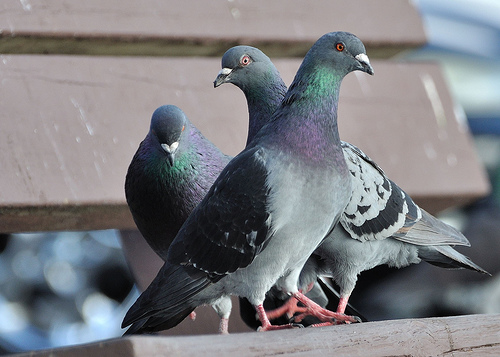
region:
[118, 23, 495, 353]
Three pigeons are standing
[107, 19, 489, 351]
Pigeons are all looking different ways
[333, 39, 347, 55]
Pigeon's eye is orange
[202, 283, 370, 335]
Pigeons' feet are pink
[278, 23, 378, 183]
Pigeon has green and purple on neck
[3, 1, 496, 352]
Pigeons are on a bench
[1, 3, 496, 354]
Bench is made of wood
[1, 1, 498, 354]
Bench is brown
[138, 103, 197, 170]
Pigeon is looking evil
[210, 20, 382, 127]
Their heads are facing opposite ways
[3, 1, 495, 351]
pigeons on a dark brown park bench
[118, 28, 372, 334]
green purple black and tan pigeon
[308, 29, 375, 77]
head of a pigeon with a brown eye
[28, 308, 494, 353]
piece of cracked wood in the seat of a bench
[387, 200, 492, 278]
long gray tail feathers of a pigeon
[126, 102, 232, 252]
blue green and purple pigeon looking down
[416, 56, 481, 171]
pigeon droppings on a back of a park bench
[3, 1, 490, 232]
two boards on the back of a park bench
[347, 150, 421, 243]
black stripes on the wing of a pigeon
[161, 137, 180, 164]
beak of a pigeon with white markings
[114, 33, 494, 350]
Three pigeons standing together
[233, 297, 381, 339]
red legs of pigeons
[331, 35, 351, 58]
orange eye of pigeon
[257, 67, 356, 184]
green and purple on pigeon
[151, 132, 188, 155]
white on beak of pigeon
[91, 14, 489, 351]
three pigeons on a bench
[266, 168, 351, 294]
gray belly of pigeon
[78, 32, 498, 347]
three birds on a bench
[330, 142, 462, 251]
gray and black feathers on side of bird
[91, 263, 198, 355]
long black tailfeathers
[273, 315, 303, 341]
part of a cklaw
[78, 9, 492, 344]
Three pigeons on a wooden park bench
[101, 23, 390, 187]
Pigeon heads with multicolored feathers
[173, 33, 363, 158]
Red eyes of pigeons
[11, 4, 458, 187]
Pigeon dropping on wooden park bench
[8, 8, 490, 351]
Brown wooden park bench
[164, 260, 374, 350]
Reddish orange feet of pigeons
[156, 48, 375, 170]
Black beaks with white tops of pigeons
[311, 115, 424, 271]
Lighter colored pigeon wing feathers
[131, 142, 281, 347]
Darker colored pigeon wing feathers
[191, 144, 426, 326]
Light gray colored feathers on abdomens of pigeons